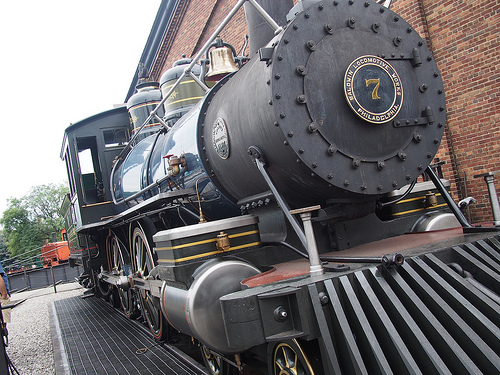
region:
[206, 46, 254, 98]
gold bell on train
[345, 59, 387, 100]
brown number on train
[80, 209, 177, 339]
black wheels on train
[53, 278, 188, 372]
train on black grated platform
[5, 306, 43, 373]
grey gravel next to train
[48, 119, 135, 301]
black control room on train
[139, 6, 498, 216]
red brick building behind train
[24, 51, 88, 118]
grey and cloudy sky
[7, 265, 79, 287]
black wall in distance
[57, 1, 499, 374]
Train engine sitting on display.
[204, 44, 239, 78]
Train engine has a golden bell.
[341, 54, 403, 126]
Locomotive engine #7 emblem on front of train.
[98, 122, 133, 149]
Train engine has a window.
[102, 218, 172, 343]
Train engine has two large wheels on outside.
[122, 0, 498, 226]
Train engine located in front of red brick building.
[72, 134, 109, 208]
Train engine has a door.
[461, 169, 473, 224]
Wooden handle leaning up against building.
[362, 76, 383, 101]
The number 7 is gold in color.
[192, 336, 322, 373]
Train engine has two smaller wheels on outside.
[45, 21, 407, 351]
black locomotive near building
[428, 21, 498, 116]
red brick on building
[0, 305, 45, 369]
grey gravel near train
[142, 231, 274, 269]
orange stripe on train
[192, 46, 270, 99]
gold bell on train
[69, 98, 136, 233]
black carriage on train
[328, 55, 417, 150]
gold number on train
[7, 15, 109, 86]
sky is bright grey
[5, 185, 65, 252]
green trees in distance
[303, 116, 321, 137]
The screw is black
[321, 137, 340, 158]
The screw is black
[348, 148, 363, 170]
The screw is black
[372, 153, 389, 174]
The screw is black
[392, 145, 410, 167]
The screw is black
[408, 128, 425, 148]
The screw is black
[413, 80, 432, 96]
The screw is black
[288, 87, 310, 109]
The screw is black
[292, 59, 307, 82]
The screw is black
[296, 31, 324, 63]
The screw is black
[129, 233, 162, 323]
a wheel of a train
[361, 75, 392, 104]
number 7 on the engine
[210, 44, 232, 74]
a bell on the train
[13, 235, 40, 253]
green leaves in the distant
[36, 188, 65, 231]
branches of a tree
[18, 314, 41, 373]
pebbles on the ground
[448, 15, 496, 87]
bricks on the wall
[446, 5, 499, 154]
the wall of a building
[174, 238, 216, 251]
a yellow stripe on the train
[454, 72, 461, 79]
A brick in a wall.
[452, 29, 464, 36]
A brick in a wall.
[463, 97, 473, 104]
A brick in a wall.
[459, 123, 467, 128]
A brick in a wall.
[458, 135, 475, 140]
A brick in a wall.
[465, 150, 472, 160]
A brick in a wall.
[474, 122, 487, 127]
A brick in a wall.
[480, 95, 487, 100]
A brick in a wall.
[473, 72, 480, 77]
A brick in a wall.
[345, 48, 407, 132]
number 7 on a train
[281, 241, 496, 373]
cattle guard on a train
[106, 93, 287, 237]
engine on a train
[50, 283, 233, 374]
black set of train tracks